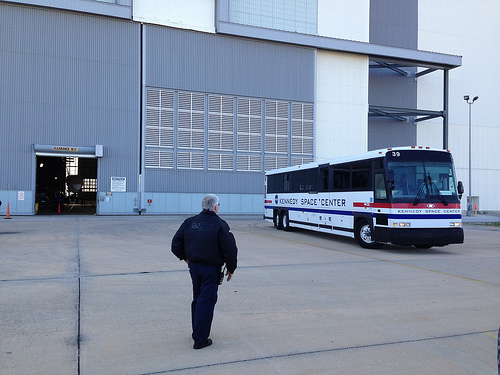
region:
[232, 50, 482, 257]
a bus parks in front a building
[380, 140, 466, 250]
front of bus is color red, white and blue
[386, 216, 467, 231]
two headlights of bus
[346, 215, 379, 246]
front wheel of bus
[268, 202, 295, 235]
back wheel of bus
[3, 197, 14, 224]
an orange cone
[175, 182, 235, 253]
man has gray hair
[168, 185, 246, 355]
man wearing blue clothes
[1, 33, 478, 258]
a building color gray and white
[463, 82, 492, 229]
a light on the sidewalk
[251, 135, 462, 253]
Large space center tour bus.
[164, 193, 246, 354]
Bus driver walking towards the bus.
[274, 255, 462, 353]
Parking lot for the bus.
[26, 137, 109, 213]
Garage door opening in the building.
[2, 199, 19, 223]
Small orange cone in the lot.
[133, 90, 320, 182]
Many windows in the building.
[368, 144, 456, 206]
Large front windshield for the bus.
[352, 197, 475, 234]
Red white and blue trim on the bus.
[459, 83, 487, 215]
Tall light in the parking lot.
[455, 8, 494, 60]
Pale blue sky in the distance.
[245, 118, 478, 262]
Bus parked at building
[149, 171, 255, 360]
Man with grey hair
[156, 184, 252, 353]
Man in dark colored jacket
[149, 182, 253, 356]
Man in dark colored pants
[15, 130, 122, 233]
Opening to building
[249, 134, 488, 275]
Bus is white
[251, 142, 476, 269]
Bus has red and blue stripes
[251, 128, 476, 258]
Bus has yellow lights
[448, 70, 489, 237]
Street lamp is off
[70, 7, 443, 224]
Large blue and white building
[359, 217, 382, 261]
a tire on a bus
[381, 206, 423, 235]
lights on the front of the bus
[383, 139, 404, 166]
a number on the bus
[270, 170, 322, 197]
windows on the side of the bus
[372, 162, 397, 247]
a dorr on the bus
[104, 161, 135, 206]
a sign on a building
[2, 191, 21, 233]
orange cone outside the building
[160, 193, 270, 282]
a man wearing a jacket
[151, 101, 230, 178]
windows in the building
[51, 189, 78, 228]
a cone inside the building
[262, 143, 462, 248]
a large white bus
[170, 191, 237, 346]
man with gray hair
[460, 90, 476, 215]
a tall light pole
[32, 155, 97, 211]
an open garage door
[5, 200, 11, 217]
orange cone to left of open garage door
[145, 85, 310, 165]
large set up windows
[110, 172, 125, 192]
white sign to right of open garage door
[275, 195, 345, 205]
words written on the side of the bus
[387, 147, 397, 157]
white numbers above the bus windshield in upper left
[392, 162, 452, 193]
the bus windshield